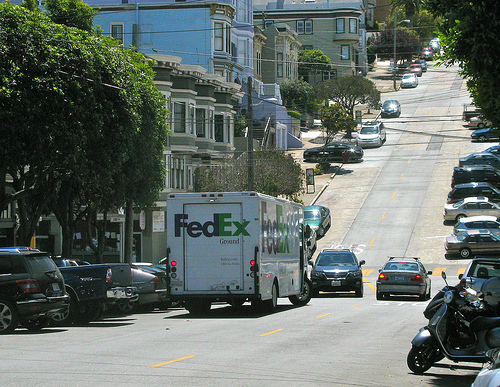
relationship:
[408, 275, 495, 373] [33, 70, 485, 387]
motorcycle on street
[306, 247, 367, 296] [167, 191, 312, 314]
suv by truck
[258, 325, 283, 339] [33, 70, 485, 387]
line on street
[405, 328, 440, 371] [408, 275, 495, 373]
front of motorcycle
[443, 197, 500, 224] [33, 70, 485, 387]
car by street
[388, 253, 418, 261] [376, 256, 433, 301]
rack on car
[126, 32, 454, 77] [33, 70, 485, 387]
lines above street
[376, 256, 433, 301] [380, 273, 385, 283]
car has brake light